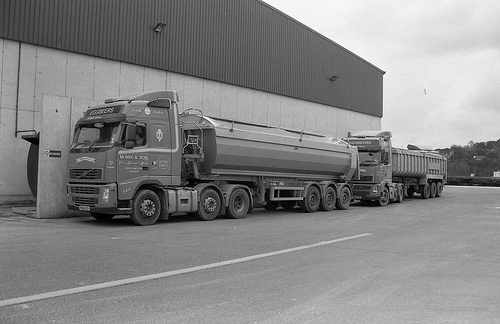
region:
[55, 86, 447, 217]
trucks against the building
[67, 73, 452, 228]
trucks against the building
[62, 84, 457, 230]
trucks against the building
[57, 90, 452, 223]
trucks against the building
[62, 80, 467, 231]
trucks against the building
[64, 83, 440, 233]
trucks against the building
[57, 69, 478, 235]
trucks against the building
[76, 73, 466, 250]
trucks against the building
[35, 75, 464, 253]
trucks against the building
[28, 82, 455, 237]
trucks against the building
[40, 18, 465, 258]
two trucks in front of a building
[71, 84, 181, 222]
the cab of a truck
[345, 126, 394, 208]
the cab of a truck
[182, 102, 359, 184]
the tanker of a truck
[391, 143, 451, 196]
the bed of a dump truck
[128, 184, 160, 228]
the wheel of a truck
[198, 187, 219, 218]
the wheel of a truck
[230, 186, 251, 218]
the wheel of a truck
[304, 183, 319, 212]
the wheel of a truck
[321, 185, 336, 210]
the wheel of a truck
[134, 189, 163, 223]
the rubber wheel of the truck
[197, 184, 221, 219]
the rubber wheel of the truck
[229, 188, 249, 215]
the rubber wheel of the truck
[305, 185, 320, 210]
the rubber wheel of the truck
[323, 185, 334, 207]
the rubber wheel of the truck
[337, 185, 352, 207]
the rubber wheel of the truck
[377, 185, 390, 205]
the rubber wheel of the truck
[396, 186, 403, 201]
the rubber wheel of the truck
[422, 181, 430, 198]
the rubber wheel of the truck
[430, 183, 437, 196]
the rubber wheel of the truck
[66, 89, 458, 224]
two trucks on the road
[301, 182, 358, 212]
three wheels on the back of the truck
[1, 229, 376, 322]
white line on the road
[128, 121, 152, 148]
window on the side of the door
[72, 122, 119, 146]
windshield on the front of the truck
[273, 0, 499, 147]
thick clouds in the sky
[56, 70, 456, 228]
truck parked behind another truck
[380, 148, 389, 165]
mirror on the side of the truck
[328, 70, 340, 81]
light high up on the building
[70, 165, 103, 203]
vents on the front of the truck